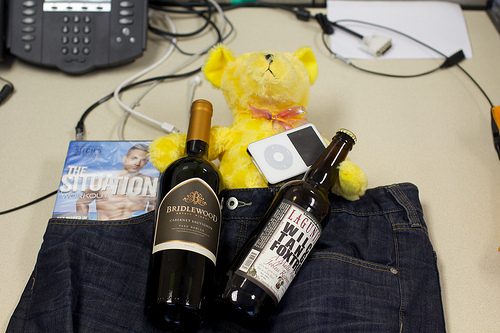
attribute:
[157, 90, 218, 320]
wine — red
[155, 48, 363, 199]
teddy bear — yellow, stuffed, bright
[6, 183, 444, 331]
jeans — blue, denim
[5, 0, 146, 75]
telephone — black, dark grey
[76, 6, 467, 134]
cables — black, gre, white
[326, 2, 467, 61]
paper — white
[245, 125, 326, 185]
ipod — 4th generation, white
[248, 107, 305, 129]
bow tie — red, pink, orange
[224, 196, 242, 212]
button — silver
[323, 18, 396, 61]
cable — dvi-d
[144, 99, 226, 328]
wine — regular sized, dark, bridlewood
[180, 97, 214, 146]
wrapping — golden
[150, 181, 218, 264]
label — black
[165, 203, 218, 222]
writing — white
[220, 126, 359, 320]
bottle — craft, brown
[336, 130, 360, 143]
cap — metal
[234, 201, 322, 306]
label — white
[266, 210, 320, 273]
writing — red, black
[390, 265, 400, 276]
rivet — silver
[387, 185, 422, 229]
belt loop — dark blue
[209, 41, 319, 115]
head — yellow, stuffed